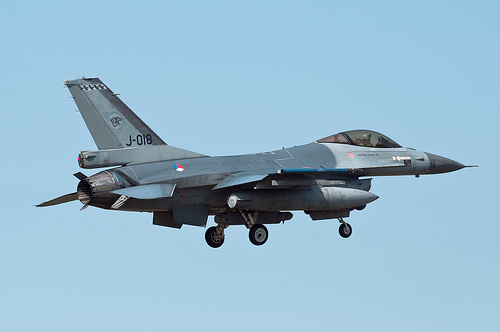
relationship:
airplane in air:
[36, 73, 477, 251] [2, 5, 498, 328]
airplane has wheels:
[36, 73, 477, 251] [192, 216, 364, 254]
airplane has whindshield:
[36, 73, 477, 251] [344, 122, 404, 149]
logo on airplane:
[170, 158, 190, 179] [36, 73, 477, 251]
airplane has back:
[36, 73, 477, 251] [24, 54, 185, 243]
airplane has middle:
[36, 73, 477, 251] [221, 145, 286, 248]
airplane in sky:
[36, 73, 477, 251] [4, 7, 491, 330]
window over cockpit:
[312, 122, 408, 149] [319, 124, 419, 169]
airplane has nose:
[36, 73, 477, 251] [426, 147, 480, 179]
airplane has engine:
[36, 73, 477, 251] [35, 160, 133, 216]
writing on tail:
[115, 129, 160, 152] [57, 67, 173, 148]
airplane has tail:
[36, 73, 477, 251] [62, 67, 162, 154]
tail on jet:
[60, 65, 171, 158] [36, 76, 498, 256]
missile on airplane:
[300, 182, 380, 214] [36, 73, 477, 251]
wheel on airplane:
[248, 218, 270, 248] [39, 73, 479, 253]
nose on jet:
[426, 150, 487, 180] [36, 76, 498, 256]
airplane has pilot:
[36, 73, 477, 251] [354, 128, 374, 150]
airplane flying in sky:
[36, 73, 477, 251] [4, 7, 491, 330]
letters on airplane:
[115, 128, 156, 147] [36, 73, 477, 251]